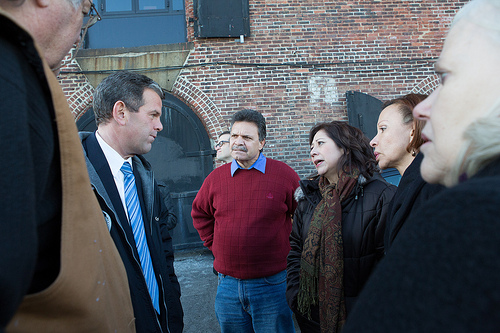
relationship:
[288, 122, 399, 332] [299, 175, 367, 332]
woman wearing a scarf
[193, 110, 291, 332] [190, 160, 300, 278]
man wearing a sweater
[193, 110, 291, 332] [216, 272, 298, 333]
man wearing jeans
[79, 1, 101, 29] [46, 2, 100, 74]
glasses on face